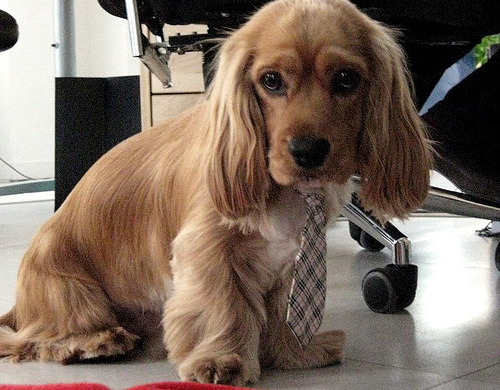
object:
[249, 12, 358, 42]
dog hair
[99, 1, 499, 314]
chair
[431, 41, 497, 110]
gap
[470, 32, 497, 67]
trees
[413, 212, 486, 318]
sunlight reflection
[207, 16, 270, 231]
dogs ears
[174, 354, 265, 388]
paw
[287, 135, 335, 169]
nose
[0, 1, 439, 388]
dog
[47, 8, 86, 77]
pole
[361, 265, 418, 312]
wheel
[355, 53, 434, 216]
hair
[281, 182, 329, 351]
tie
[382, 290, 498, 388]
floor